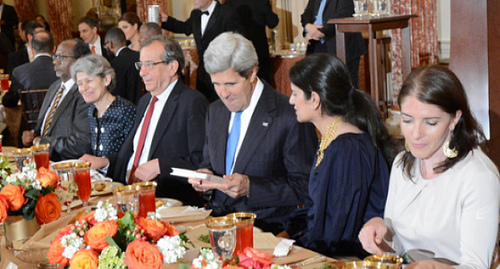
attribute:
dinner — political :
[0, 141, 408, 267]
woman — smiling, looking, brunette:
[358, 64, 499, 267]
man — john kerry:
[189, 31, 313, 238]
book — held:
[168, 167, 232, 184]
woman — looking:
[289, 53, 391, 259]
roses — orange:
[1, 185, 28, 223]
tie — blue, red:
[223, 109, 242, 175]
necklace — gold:
[312, 118, 348, 169]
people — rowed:
[23, 39, 500, 267]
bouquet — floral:
[1, 166, 62, 230]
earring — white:
[442, 132, 461, 158]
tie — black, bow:
[201, 9, 208, 17]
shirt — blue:
[312, 1, 328, 45]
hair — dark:
[204, 31, 261, 79]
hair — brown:
[396, 65, 489, 183]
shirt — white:
[384, 144, 498, 268]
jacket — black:
[196, 80, 314, 231]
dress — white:
[381, 145, 496, 268]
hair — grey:
[70, 54, 119, 91]